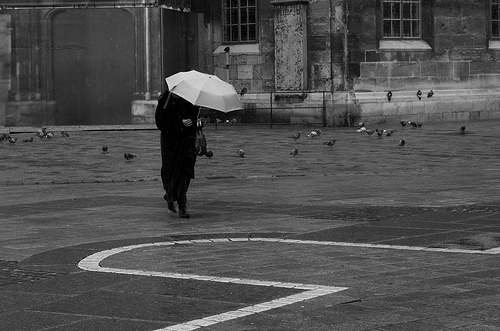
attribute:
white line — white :
[92, 227, 497, 318]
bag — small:
[194, 125, 211, 160]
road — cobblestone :
[27, 107, 495, 194]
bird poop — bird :
[249, 298, 306, 326]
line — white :
[74, 234, 496, 329]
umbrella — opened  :
[164, 67, 245, 112]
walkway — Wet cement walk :
[0, 182, 499, 329]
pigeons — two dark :
[96, 140, 143, 162]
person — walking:
[147, 66, 238, 221]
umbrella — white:
[166, 64, 246, 114]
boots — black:
[164, 183, 188, 215]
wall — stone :
[365, 8, 446, 59]